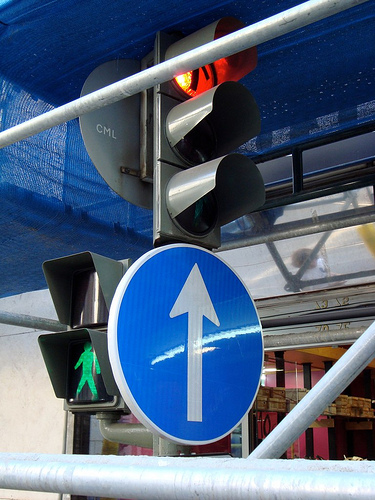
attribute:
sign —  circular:
[49, 17, 265, 220]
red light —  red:
[174, 22, 263, 125]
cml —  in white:
[96, 124, 117, 141]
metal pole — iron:
[25, 451, 179, 495]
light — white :
[37, 326, 130, 413]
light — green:
[63, 338, 111, 405]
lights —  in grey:
[140, 13, 268, 265]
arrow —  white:
[168, 262, 219, 422]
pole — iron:
[2, 0, 370, 153]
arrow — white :
[170, 262, 212, 426]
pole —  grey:
[0, 318, 375, 498]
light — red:
[182, 39, 274, 100]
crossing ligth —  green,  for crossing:
[58, 329, 119, 407]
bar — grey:
[0, 110, 63, 150]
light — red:
[166, 62, 223, 97]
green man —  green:
[75, 343, 100, 403]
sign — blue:
[134, 240, 230, 311]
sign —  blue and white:
[101, 231, 271, 448]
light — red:
[163, 15, 257, 97]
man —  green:
[71, 342, 103, 396]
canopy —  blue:
[1, 80, 166, 301]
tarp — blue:
[0, 5, 370, 228]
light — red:
[165, 40, 220, 95]